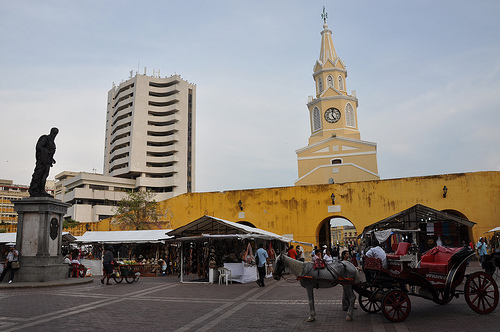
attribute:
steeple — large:
[320, 5, 330, 30]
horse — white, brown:
[271, 254, 362, 322]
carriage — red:
[357, 237, 499, 322]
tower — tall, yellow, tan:
[305, 5, 362, 143]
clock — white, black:
[322, 107, 342, 123]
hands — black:
[329, 108, 338, 121]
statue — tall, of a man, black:
[30, 125, 59, 196]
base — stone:
[11, 196, 70, 279]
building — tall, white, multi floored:
[54, 63, 198, 222]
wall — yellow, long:
[61, 172, 499, 267]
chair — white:
[221, 259, 259, 285]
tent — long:
[75, 214, 317, 285]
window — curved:
[148, 79, 181, 87]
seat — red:
[418, 243, 457, 273]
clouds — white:
[360, 76, 500, 143]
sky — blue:
[1, 0, 500, 191]